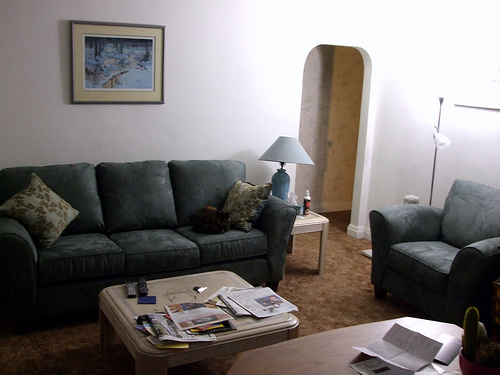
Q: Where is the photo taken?
A: Living room.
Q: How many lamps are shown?
A: Two.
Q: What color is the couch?
A: Blue.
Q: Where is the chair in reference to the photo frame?
A: Right.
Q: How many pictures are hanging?
A: One.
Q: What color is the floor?
A: Brown.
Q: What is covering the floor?
A: Carpet.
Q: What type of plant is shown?
A: Cactus.